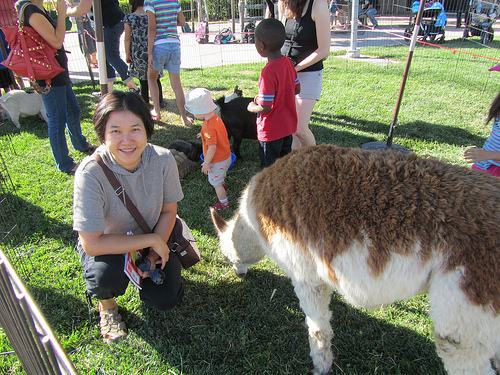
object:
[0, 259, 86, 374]
side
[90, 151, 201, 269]
bag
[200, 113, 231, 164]
shirt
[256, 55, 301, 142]
shirt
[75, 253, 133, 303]
short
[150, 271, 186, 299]
pant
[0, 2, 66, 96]
bag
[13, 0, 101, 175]
woman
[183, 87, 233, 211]
boy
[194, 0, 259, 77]
fence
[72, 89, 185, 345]
person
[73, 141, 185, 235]
shirt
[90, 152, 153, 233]
strap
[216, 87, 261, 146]
stroller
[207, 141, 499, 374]
animal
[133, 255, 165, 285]
sunglasses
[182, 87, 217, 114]
hat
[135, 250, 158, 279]
hand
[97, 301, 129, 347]
shoe